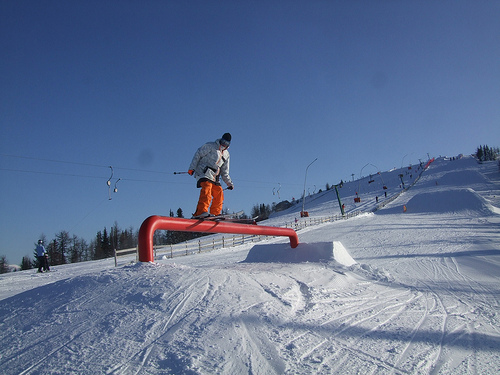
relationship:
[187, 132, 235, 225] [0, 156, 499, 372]
man on slope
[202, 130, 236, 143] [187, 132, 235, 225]
head on man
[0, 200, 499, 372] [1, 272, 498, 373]
tracks on snow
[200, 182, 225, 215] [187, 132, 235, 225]
pants on man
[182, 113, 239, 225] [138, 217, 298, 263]
man on pipe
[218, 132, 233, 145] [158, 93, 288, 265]
hat on man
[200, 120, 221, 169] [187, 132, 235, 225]
coat on man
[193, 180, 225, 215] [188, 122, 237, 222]
pants on man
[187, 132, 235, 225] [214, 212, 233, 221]
man on ski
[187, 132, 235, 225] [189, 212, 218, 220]
man on ski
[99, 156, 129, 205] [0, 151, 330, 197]
ski lift on wires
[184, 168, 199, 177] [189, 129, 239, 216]
hand on person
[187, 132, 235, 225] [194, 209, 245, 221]
man on ski